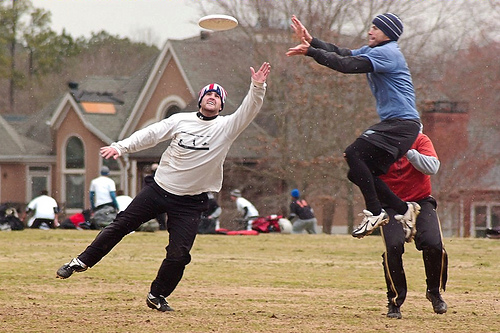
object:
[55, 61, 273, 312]
man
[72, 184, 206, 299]
pants